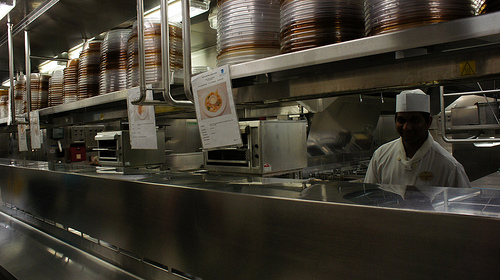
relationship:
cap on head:
[394, 89, 431, 114] [388, 88, 434, 144]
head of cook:
[394, 90, 434, 143] [362, 87, 473, 189]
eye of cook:
[411, 118, 422, 127] [362, 87, 473, 189]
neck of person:
[381, 133, 448, 168] [333, 79, 468, 196]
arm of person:
[440, 161, 471, 187] [370, 87, 458, 186]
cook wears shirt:
[362, 87, 473, 189] [361, 130, 471, 189]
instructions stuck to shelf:
[189, 62, 243, 149] [192, 0, 498, 95]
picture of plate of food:
[194, 82, 231, 117] [206, 95, 220, 108]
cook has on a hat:
[362, 87, 473, 189] [391, 85, 430, 109]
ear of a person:
[422, 108, 439, 135] [355, 87, 477, 196]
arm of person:
[440, 153, 472, 187] [441, 150, 470, 186]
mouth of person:
[397, 129, 425, 143] [361, 79, 474, 189]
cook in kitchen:
[362, 87, 473, 189] [0, 1, 499, 278]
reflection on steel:
[344, 176, 455, 224] [2, 156, 494, 279]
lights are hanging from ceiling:
[0, 0, 212, 85] [0, 2, 222, 88]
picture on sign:
[197, 88, 231, 117] [189, 64, 240, 155]